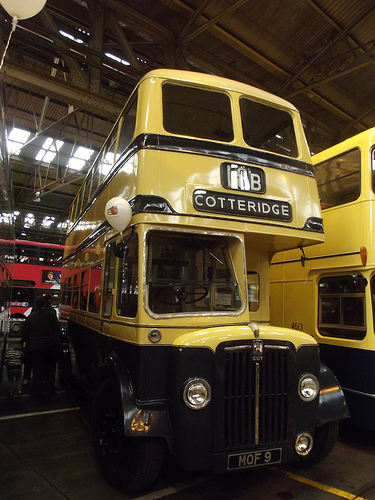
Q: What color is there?
A: Yellow.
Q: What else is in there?
A: Other trucks.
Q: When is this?
A: Daytime.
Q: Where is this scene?
A: Truck garage.